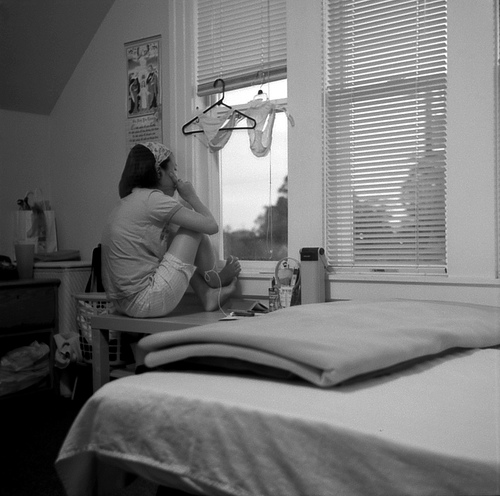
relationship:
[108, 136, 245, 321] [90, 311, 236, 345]
girl on table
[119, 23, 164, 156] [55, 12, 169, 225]
calendar on wall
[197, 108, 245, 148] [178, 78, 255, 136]
panties on hanger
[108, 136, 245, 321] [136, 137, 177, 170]
girl wearing bandana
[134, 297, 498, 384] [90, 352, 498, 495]
blanket on sheet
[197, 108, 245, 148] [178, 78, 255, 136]
laundry on hanger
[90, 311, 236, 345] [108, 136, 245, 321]
table under girl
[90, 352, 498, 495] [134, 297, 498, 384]
bed under blanket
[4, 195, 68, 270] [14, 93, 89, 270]
bag in corner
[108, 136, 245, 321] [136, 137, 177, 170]
girl with scarf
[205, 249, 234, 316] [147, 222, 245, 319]
cord on legs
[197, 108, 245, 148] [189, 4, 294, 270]
panties in window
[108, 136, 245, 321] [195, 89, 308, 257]
girl looking out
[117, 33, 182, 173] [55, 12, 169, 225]
poster on wall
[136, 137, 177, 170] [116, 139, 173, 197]
bandana on hair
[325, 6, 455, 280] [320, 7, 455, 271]
blinds over window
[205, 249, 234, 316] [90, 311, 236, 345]
cord on table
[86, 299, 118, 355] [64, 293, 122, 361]
clothes in basket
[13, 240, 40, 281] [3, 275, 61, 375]
cup on desk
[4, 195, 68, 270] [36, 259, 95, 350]
bag on laundry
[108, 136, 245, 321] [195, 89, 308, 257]
girl looking outside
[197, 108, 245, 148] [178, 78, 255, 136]
clothes on hanger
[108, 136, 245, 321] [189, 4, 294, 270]
girl looking out window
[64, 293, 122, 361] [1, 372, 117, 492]
basket on floor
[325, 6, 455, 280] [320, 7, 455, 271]
blinds on window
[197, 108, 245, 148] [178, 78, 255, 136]
panties with hanger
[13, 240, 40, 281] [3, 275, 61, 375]
cup with desk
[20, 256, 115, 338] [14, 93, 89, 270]
hamper i corner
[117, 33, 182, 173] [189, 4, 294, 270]
poster beside window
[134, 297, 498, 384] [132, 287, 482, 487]
blanket on bed